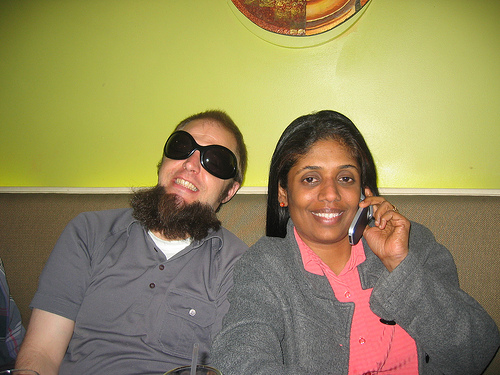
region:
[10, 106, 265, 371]
man in gray shirt grinning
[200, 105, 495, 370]
woman in pink shirt and gray jacket talking on cell phone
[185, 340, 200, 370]
clear plastic straw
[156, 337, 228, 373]
cylindrical plastic drink cup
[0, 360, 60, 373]
rim of cup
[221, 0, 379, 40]
circular brown orange and yellow piece of art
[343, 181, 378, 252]
gray and black flip cell phone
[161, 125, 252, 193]
large black sunglasses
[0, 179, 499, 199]
white wooden strip on wall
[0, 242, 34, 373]
blue white and red plaid shirt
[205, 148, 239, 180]
Black eyeglasses in the photo.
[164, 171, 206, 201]
A man smiling in the photo.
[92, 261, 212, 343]
A gray t-shirt in the photo.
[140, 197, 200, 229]
Long beard in the photo.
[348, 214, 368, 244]
A mobile phone in the picture.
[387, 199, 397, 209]
A ring in the photo.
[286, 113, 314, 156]
Long black hair in the photo.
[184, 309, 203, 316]
A white button in the photo.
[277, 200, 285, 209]
Red earing in the picture.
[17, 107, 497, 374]
A man and woman seated.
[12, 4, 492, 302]
The wall is green and brown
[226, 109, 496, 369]
The woman is on the phone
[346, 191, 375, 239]
The phone is silver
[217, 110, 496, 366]
The woman is wearing a pink shirt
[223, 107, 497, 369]
The woman is wearing a grey jacket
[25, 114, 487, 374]
The woman is sitting next to a man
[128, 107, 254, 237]
The man is wearing sunglasses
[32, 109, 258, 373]
The man is wearing a grey shirt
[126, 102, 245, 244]
The man has a brown beard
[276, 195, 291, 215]
The women is wearing round, red earrings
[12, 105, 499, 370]
the man and woman sitting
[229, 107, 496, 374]
the woman on the phone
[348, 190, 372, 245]
the cell phone to the woman's ear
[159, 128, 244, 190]
the sunglasses on the man's face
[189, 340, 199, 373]
the clear straw in the cup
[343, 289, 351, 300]
the button on the woman's shirt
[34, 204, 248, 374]
the man's short sleeved shirt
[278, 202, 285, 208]
the earring in the woman's ear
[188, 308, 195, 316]
the button on the man's pocket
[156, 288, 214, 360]
the pocket on the man's shirt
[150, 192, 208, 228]
man has a long beard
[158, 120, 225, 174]
man is wearing sunglasses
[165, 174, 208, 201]
man is showing his teeth smiling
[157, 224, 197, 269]
man has a white shirt under his button shirt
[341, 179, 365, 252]
woman is talking on a cellphone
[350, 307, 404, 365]
woman's shirt is pink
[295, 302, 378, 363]
woman is wearing a grey jacket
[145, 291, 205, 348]
man has a pocket on the front of his shirt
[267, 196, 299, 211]
woman is wearing earrings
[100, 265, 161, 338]
man has on a grey button shirt